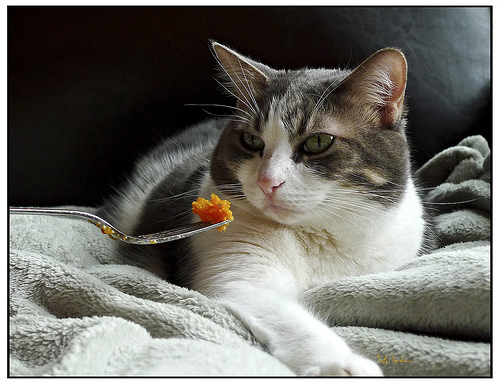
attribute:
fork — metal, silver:
[10, 192, 237, 248]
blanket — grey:
[12, 162, 497, 384]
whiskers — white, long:
[141, 180, 469, 245]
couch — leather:
[9, 10, 499, 183]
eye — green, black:
[299, 129, 336, 157]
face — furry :
[199, 34, 420, 236]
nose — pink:
[253, 174, 285, 203]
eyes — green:
[230, 122, 337, 163]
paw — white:
[295, 349, 387, 379]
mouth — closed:
[259, 196, 301, 223]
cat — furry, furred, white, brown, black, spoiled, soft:
[106, 42, 427, 382]